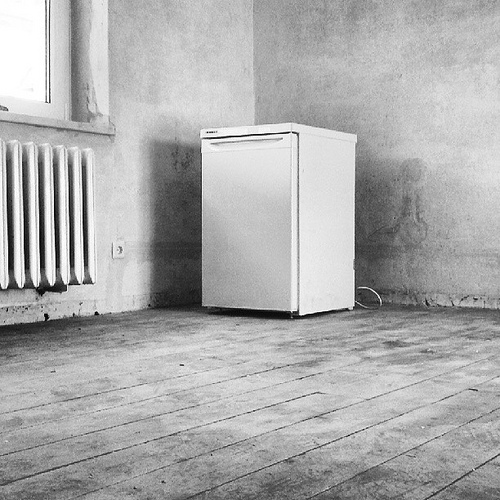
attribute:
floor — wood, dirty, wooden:
[1, 311, 494, 495]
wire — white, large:
[355, 284, 384, 310]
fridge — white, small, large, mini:
[196, 122, 360, 319]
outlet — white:
[113, 238, 129, 258]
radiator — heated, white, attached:
[0, 140, 103, 291]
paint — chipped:
[359, 286, 500, 309]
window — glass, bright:
[2, 6, 51, 108]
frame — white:
[2, 2, 73, 121]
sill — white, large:
[2, 100, 114, 137]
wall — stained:
[369, 160, 431, 262]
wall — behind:
[255, 3, 498, 310]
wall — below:
[2, 0, 259, 327]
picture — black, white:
[1, 0, 500, 499]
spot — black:
[394, 155, 428, 187]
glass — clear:
[0, 2, 49, 106]